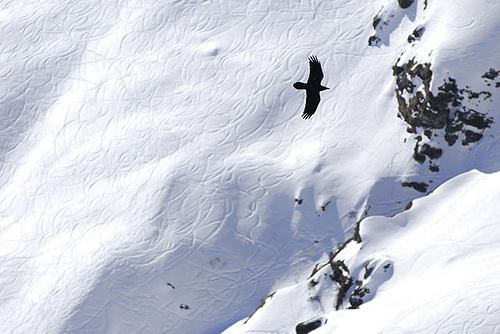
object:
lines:
[203, 101, 269, 155]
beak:
[320, 80, 328, 96]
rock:
[398, 181, 438, 199]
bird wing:
[304, 54, 325, 87]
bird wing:
[300, 88, 320, 118]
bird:
[294, 54, 332, 120]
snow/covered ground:
[10, 22, 239, 268]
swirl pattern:
[115, 146, 140, 173]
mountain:
[0, 0, 500, 330]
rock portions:
[391, 56, 494, 175]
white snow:
[31, 59, 221, 284]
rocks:
[327, 260, 374, 310]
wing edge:
[306, 95, 311, 110]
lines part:
[245, 233, 265, 251]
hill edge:
[422, 168, 470, 208]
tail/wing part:
[291, 81, 316, 89]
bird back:
[293, 80, 309, 91]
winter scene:
[0, 0, 500, 334]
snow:
[0, 0, 500, 334]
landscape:
[0, 0, 500, 333]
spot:
[413, 86, 466, 136]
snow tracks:
[190, 70, 295, 216]